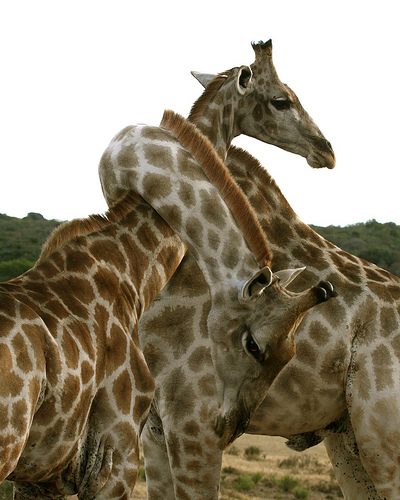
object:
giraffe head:
[191, 39, 336, 171]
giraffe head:
[206, 266, 341, 451]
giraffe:
[0, 36, 337, 500]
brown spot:
[89, 240, 126, 273]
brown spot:
[87, 386, 117, 433]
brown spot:
[156, 201, 182, 233]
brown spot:
[20, 323, 62, 387]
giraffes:
[0, 35, 399, 497]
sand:
[223, 445, 338, 498]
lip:
[205, 415, 231, 455]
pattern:
[48, 262, 150, 396]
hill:
[0, 211, 398, 281]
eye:
[272, 97, 290, 110]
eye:
[246, 333, 260, 358]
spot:
[136, 221, 160, 253]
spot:
[60, 326, 80, 370]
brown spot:
[143, 264, 163, 313]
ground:
[236, 463, 281, 479]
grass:
[275, 474, 315, 495]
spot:
[198, 189, 227, 228]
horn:
[251, 38, 273, 72]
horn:
[287, 287, 328, 312]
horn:
[308, 279, 338, 301]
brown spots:
[248, 186, 277, 212]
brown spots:
[259, 216, 293, 248]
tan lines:
[284, 237, 298, 254]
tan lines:
[318, 265, 336, 279]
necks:
[56, 93, 344, 310]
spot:
[61, 373, 81, 413]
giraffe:
[98, 109, 398, 500]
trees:
[0, 208, 64, 278]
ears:
[190, 70, 254, 95]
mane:
[160, 107, 273, 267]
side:
[36, 255, 145, 429]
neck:
[97, 120, 236, 305]